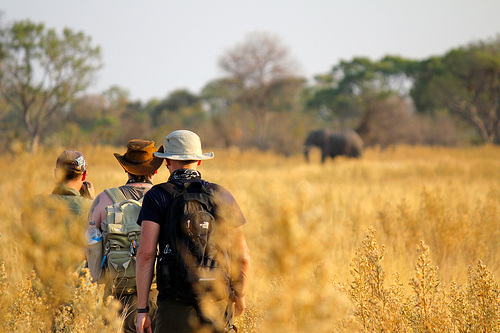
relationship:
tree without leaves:
[221, 37, 313, 91] [451, 59, 494, 81]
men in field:
[58, 141, 255, 324] [296, 166, 485, 313]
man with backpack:
[165, 130, 267, 302] [168, 198, 234, 303]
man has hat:
[165, 130, 267, 302] [161, 131, 214, 164]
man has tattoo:
[165, 130, 267, 302] [90, 193, 109, 218]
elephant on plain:
[305, 127, 367, 165] [5, 117, 484, 314]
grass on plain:
[296, 166, 485, 313] [16, 135, 482, 325]